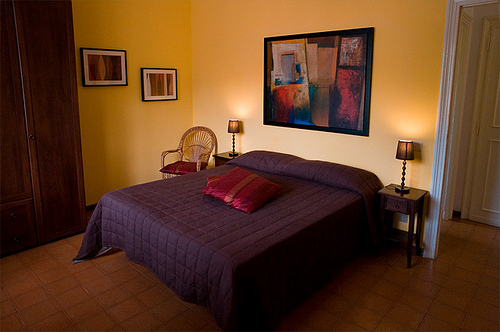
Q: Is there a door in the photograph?
A: Yes, there is a door.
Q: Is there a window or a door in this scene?
A: Yes, there is a door.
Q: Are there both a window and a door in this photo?
A: No, there is a door but no windows.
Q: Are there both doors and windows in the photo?
A: No, there is a door but no windows.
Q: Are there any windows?
A: No, there are no windows.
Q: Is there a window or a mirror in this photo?
A: No, there are no windows or mirrors.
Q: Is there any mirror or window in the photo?
A: No, there are no windows or mirrors.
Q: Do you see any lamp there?
A: Yes, there is a lamp.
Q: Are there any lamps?
A: Yes, there is a lamp.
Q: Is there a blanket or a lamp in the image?
A: Yes, there is a lamp.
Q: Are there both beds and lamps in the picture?
A: Yes, there are both a lamp and a bed.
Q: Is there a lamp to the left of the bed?
A: No, the lamp is to the right of the bed.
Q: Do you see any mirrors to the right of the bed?
A: No, there is a lamp to the right of the bed.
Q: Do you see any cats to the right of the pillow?
A: No, there is a lamp to the right of the pillow.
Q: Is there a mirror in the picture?
A: No, there are no mirrors.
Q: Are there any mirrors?
A: No, there are no mirrors.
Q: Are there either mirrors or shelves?
A: No, there are no mirrors or shelves.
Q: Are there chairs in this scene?
A: Yes, there is a chair.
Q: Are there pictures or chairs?
A: Yes, there is a chair.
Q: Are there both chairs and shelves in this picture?
A: No, there is a chair but no shelves.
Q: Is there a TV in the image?
A: No, there are no televisions.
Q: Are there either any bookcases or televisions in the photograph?
A: No, there are no televisions or bookcases.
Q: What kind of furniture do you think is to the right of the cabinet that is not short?
A: The piece of furniture is a chair.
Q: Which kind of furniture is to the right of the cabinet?
A: The piece of furniture is a chair.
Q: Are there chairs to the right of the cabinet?
A: Yes, there is a chair to the right of the cabinet.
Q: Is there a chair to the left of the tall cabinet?
A: No, the chair is to the right of the cabinet.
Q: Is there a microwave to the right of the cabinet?
A: No, there is a chair to the right of the cabinet.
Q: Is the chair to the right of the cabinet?
A: Yes, the chair is to the right of the cabinet.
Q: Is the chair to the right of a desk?
A: No, the chair is to the right of the cabinet.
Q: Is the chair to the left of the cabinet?
A: No, the chair is to the right of the cabinet.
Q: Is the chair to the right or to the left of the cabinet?
A: The chair is to the right of the cabinet.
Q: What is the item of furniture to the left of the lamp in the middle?
A: The piece of furniture is a chair.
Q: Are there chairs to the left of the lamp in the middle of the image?
A: Yes, there is a chair to the left of the lamp.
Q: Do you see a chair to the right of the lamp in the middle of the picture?
A: No, the chair is to the left of the lamp.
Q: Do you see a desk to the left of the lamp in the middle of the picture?
A: No, there is a chair to the left of the lamp.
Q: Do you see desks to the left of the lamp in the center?
A: No, there is a chair to the left of the lamp.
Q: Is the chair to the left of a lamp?
A: Yes, the chair is to the left of a lamp.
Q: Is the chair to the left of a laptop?
A: No, the chair is to the left of a lamp.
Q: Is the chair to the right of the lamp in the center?
A: No, the chair is to the left of the lamp.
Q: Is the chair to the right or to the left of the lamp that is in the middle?
A: The chair is to the left of the lamp.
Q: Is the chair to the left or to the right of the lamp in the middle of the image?
A: The chair is to the left of the lamp.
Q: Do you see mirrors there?
A: No, there are no mirrors.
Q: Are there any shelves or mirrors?
A: No, there are no mirrors or shelves.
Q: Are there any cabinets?
A: Yes, there is a cabinet.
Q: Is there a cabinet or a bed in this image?
A: Yes, there is a cabinet.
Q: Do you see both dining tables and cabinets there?
A: No, there is a cabinet but no dining tables.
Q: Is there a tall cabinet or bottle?
A: Yes, there is a tall cabinet.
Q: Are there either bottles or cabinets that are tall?
A: Yes, the cabinet is tall.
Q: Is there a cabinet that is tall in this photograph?
A: Yes, there is a tall cabinet.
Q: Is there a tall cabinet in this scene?
A: Yes, there is a tall cabinet.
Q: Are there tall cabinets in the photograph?
A: Yes, there is a tall cabinet.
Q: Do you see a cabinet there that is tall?
A: Yes, there is a cabinet that is tall.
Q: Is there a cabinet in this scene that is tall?
A: Yes, there is a cabinet that is tall.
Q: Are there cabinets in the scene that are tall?
A: Yes, there is a cabinet that is tall.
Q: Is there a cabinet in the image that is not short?
A: Yes, there is a tall cabinet.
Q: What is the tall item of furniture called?
A: The piece of furniture is a cabinet.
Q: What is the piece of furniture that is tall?
A: The piece of furniture is a cabinet.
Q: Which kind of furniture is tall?
A: The furniture is a cabinet.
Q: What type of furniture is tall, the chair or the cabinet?
A: The cabinet is tall.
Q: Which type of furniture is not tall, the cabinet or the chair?
A: The chair is not tall.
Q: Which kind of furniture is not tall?
A: The furniture is a chair.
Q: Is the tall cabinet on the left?
A: Yes, the cabinet is on the left of the image.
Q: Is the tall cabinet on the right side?
A: No, the cabinet is on the left of the image.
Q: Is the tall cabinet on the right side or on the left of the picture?
A: The cabinet is on the left of the image.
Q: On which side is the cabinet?
A: The cabinet is on the left of the image.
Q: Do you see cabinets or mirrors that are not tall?
A: No, there is a cabinet but it is tall.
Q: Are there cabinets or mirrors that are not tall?
A: No, there is a cabinet but it is tall.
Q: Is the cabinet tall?
A: Yes, the cabinet is tall.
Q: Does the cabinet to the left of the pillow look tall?
A: Yes, the cabinet is tall.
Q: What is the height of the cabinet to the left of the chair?
A: The cabinet is tall.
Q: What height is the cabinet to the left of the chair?
A: The cabinet is tall.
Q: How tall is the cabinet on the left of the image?
A: The cabinet is tall.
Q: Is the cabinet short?
A: No, the cabinet is tall.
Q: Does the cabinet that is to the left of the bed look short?
A: No, the cabinet is tall.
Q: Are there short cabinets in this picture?
A: No, there is a cabinet but it is tall.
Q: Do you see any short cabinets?
A: No, there is a cabinet but it is tall.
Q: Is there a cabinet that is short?
A: No, there is a cabinet but it is tall.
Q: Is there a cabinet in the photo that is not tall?
A: No, there is a cabinet but it is tall.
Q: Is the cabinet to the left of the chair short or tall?
A: The cabinet is tall.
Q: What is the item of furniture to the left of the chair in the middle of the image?
A: The piece of furniture is a cabinet.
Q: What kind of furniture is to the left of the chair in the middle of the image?
A: The piece of furniture is a cabinet.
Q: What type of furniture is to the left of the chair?
A: The piece of furniture is a cabinet.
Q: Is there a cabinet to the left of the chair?
A: Yes, there is a cabinet to the left of the chair.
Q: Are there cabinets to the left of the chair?
A: Yes, there is a cabinet to the left of the chair.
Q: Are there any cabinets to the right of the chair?
A: No, the cabinet is to the left of the chair.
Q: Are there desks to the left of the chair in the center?
A: No, there is a cabinet to the left of the chair.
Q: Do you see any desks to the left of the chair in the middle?
A: No, there is a cabinet to the left of the chair.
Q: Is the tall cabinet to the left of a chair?
A: Yes, the cabinet is to the left of a chair.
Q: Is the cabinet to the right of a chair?
A: No, the cabinet is to the left of a chair.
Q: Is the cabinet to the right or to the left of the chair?
A: The cabinet is to the left of the chair.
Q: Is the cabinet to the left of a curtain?
A: No, the cabinet is to the left of a painting.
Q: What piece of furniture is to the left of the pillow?
A: The piece of furniture is a cabinet.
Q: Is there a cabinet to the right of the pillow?
A: No, the cabinet is to the left of the pillow.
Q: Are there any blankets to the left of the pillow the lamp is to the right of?
A: No, there is a cabinet to the left of the pillow.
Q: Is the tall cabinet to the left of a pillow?
A: Yes, the cabinet is to the left of a pillow.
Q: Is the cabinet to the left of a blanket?
A: No, the cabinet is to the left of a pillow.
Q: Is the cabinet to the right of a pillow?
A: No, the cabinet is to the left of a pillow.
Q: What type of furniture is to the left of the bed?
A: The piece of furniture is a cabinet.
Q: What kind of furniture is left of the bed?
A: The piece of furniture is a cabinet.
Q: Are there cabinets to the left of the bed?
A: Yes, there is a cabinet to the left of the bed.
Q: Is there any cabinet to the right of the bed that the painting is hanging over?
A: No, the cabinet is to the left of the bed.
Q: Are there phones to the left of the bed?
A: No, there is a cabinet to the left of the bed.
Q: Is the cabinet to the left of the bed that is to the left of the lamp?
A: Yes, the cabinet is to the left of the bed.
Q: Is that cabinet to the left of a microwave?
A: No, the cabinet is to the left of the bed.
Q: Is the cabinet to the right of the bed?
A: No, the cabinet is to the left of the bed.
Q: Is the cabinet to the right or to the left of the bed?
A: The cabinet is to the left of the bed.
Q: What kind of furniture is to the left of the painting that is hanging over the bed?
A: The piece of furniture is a cabinet.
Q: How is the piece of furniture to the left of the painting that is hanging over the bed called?
A: The piece of furniture is a cabinet.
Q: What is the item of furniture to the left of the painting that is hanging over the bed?
A: The piece of furniture is a cabinet.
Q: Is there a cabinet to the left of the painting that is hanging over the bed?
A: Yes, there is a cabinet to the left of the painting.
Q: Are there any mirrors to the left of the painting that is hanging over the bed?
A: No, there is a cabinet to the left of the painting.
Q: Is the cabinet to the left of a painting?
A: Yes, the cabinet is to the left of a painting.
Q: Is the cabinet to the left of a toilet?
A: No, the cabinet is to the left of a painting.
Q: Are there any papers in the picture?
A: No, there are no papers.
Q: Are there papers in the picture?
A: No, there are no papers.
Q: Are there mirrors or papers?
A: No, there are no papers or mirrors.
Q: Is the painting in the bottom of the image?
A: No, the painting is in the top of the image.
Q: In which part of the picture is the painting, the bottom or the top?
A: The painting is in the top of the image.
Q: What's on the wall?
A: The painting is on the wall.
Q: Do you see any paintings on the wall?
A: Yes, there is a painting on the wall.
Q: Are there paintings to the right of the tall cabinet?
A: Yes, there is a painting to the right of the cabinet.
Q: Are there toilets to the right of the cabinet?
A: No, there is a painting to the right of the cabinet.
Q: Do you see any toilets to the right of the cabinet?
A: No, there is a painting to the right of the cabinet.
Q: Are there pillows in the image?
A: Yes, there is a pillow.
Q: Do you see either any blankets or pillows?
A: Yes, there is a pillow.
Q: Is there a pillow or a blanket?
A: Yes, there is a pillow.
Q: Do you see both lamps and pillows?
A: Yes, there are both a pillow and a lamp.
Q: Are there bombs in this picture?
A: No, there are no bombs.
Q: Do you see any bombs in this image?
A: No, there are no bombs.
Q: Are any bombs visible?
A: No, there are no bombs.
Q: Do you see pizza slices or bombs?
A: No, there are no bombs or pizza slices.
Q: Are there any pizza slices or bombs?
A: No, there are no bombs or pizza slices.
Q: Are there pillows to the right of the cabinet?
A: Yes, there is a pillow to the right of the cabinet.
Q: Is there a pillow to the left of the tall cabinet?
A: No, the pillow is to the right of the cabinet.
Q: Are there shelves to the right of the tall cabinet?
A: No, there is a pillow to the right of the cabinet.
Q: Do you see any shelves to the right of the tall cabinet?
A: No, there is a pillow to the right of the cabinet.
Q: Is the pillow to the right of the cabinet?
A: Yes, the pillow is to the right of the cabinet.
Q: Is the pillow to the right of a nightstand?
A: No, the pillow is to the right of the cabinet.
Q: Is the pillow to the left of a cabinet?
A: No, the pillow is to the right of a cabinet.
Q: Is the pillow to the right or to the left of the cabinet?
A: The pillow is to the right of the cabinet.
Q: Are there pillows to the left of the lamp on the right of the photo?
A: Yes, there is a pillow to the left of the lamp.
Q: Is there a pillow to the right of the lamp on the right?
A: No, the pillow is to the left of the lamp.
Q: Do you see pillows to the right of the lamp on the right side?
A: No, the pillow is to the left of the lamp.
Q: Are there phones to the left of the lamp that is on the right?
A: No, there is a pillow to the left of the lamp.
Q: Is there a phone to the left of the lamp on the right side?
A: No, there is a pillow to the left of the lamp.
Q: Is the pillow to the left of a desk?
A: No, the pillow is to the left of the lamp.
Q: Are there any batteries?
A: No, there are no batteries.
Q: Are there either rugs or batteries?
A: No, there are no batteries or rugs.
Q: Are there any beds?
A: Yes, there is a bed.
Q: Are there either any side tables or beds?
A: Yes, there is a bed.